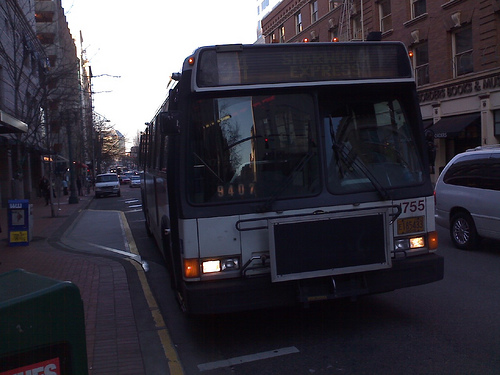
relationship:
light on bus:
[186, 260, 233, 276] [137, 44, 443, 307]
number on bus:
[397, 197, 428, 216] [137, 44, 443, 307]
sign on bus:
[189, 50, 411, 82] [137, 44, 443, 307]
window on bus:
[190, 102, 421, 192] [137, 44, 443, 307]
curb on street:
[112, 212, 173, 372] [119, 171, 499, 374]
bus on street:
[137, 44, 443, 307] [119, 171, 499, 374]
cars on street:
[92, 155, 494, 247] [119, 171, 499, 374]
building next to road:
[1, 3, 99, 196] [119, 171, 499, 374]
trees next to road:
[19, 95, 134, 197] [119, 171, 499, 374]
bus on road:
[137, 44, 443, 307] [119, 171, 499, 374]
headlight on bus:
[401, 234, 428, 250] [137, 44, 443, 307]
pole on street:
[61, 106, 80, 202] [119, 171, 499, 374]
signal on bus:
[424, 233, 438, 247] [137, 44, 443, 307]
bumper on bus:
[189, 256, 444, 307] [137, 44, 443, 307]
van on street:
[434, 151, 500, 243] [119, 171, 499, 374]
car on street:
[126, 176, 138, 186] [119, 171, 499, 374]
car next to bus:
[126, 176, 138, 186] [137, 44, 443, 307]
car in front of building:
[126, 176, 138, 186] [1, 3, 99, 196]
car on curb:
[126, 176, 138, 186] [112, 212, 173, 372]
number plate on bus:
[215, 184, 259, 201] [137, 44, 443, 307]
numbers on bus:
[215, 184, 259, 201] [137, 44, 443, 307]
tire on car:
[451, 211, 474, 244] [434, 151, 500, 243]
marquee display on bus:
[189, 50, 411, 82] [137, 44, 443, 307]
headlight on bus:
[186, 260, 233, 276] [137, 44, 443, 307]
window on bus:
[144, 127, 173, 178] [137, 44, 443, 307]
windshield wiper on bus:
[330, 128, 380, 193] [137, 44, 443, 307]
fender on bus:
[183, 269, 454, 300] [137, 44, 443, 307]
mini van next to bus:
[434, 151, 500, 243] [137, 44, 443, 307]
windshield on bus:
[190, 102, 421, 192] [137, 44, 443, 307]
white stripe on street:
[189, 346, 316, 370] [119, 171, 499, 374]